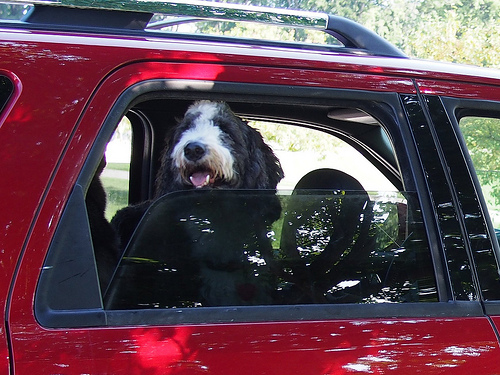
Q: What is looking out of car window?
A: Black and white dog.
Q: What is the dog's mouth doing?
A: It is panting.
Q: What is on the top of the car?
A: Roof rack.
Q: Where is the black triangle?
A: A piece of the back window.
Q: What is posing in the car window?
A: A dog.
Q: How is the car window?
A: Partially open.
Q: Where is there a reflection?
A: Car window.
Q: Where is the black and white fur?
A: Dog's coat.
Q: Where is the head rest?
A: Back front seat.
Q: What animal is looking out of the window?
A: A dog.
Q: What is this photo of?
A: A car.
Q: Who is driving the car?
A: A licensed driver.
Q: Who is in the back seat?
A: A dog.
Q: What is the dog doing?
A: Looking out the window.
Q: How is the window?
A: Rolled halfway down.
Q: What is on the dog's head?
A: Fur.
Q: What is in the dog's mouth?
A: Teeth.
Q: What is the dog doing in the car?
A: Taking a ride.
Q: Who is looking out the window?
A: Dog.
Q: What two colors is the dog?
A: Black and white.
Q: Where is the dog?
A: In the suv.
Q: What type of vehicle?
A: Suv.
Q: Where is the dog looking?
A: Out the window.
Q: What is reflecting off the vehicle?
A: Sunlight.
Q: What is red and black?
A: The suv.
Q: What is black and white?
A: The dog.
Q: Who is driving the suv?
A: There is no one driving.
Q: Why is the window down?
A: For the dog.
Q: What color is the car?
A: Red.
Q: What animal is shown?
A: A dog.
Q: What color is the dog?
A: Black and white.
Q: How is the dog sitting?
A: With head out window.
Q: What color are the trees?
A: Green.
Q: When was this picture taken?
A: Daytime.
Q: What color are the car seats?
A: Black.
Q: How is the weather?
A: Sunny.